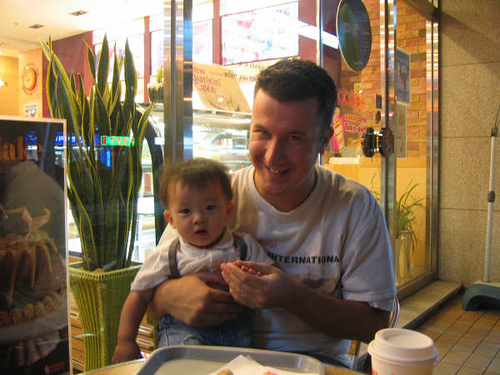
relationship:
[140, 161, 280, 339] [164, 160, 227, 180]
boy has hair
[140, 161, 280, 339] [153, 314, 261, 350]
boy wearing jeans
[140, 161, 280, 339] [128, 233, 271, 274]
boy wearing shirt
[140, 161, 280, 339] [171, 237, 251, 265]
boy wearing suspenders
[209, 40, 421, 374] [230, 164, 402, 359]
man wearing shirt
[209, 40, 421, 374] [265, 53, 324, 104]
man has hair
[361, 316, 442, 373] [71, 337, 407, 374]
coffe cup on table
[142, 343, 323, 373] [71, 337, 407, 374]
tray on table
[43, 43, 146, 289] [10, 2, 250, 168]
plant in background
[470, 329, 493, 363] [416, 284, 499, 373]
tiles on ground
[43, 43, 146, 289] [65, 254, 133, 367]
plant in vase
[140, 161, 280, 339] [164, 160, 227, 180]
baby has hair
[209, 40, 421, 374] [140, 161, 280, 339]
man holding baby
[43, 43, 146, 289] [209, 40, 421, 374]
plant behind man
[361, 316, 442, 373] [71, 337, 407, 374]
cup on table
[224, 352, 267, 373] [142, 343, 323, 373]
napkin on tray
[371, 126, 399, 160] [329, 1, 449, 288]
lock on door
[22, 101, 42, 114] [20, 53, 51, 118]
picture on wall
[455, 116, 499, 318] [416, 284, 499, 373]
scraper on floor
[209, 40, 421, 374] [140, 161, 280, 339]
man with boy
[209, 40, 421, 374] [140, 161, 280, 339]
man holding boy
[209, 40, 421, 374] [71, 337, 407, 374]
man at table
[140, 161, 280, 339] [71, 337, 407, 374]
boy at table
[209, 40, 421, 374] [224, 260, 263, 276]
man holding hand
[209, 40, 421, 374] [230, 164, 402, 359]
man wears shirt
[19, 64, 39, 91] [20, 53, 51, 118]
clock on wall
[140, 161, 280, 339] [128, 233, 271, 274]
baby wearing shirt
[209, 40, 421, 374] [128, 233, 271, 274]
man wearing shirt